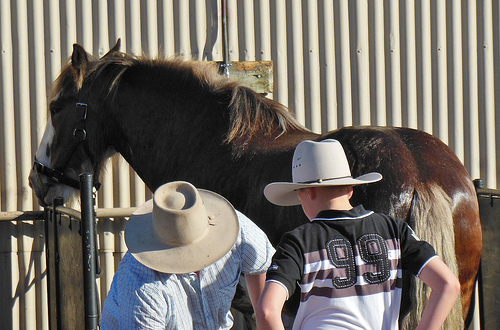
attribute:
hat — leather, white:
[252, 137, 390, 204]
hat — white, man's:
[126, 179, 238, 269]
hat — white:
[116, 178, 242, 285]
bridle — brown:
[36, 82, 101, 189]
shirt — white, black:
[301, 205, 395, 315]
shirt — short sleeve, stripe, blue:
[89, 191, 281, 327]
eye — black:
[39, 89, 71, 122]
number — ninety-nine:
[320, 230, 392, 297]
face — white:
[29, 97, 70, 208]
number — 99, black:
[326, 231, 391, 288]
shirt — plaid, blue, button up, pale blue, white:
[99, 207, 276, 329]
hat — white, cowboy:
[261, 137, 382, 207]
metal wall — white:
[328, 21, 468, 97]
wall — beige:
[330, 22, 435, 76]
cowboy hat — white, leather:
[119, 177, 241, 277]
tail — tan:
[399, 178, 466, 328]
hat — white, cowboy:
[259, 131, 387, 211]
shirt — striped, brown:
[231, 210, 426, 302]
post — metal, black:
[78, 170, 99, 327]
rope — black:
[297, 170, 360, 182]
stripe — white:
[417, 254, 437, 279]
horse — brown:
[20, 58, 480, 330]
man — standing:
[107, 164, 282, 330]